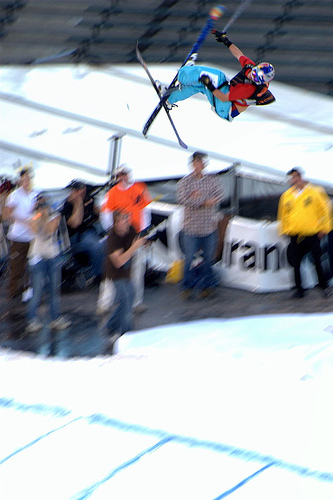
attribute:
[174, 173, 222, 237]
shirt — plaid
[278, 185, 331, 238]
jacket — yellow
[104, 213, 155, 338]
man — photographer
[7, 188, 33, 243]
shirt — white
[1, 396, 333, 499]
lines — blue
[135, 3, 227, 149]
ski's — crossed, blue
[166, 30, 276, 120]
man — airborne, competing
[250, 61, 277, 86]
helmet — blue, silver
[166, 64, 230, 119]
pants — blue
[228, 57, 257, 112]
shirt — red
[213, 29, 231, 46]
glove — black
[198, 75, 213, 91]
glove — black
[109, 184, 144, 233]
shirt — orange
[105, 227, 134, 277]
shirt — brown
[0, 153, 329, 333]
crowd — watching